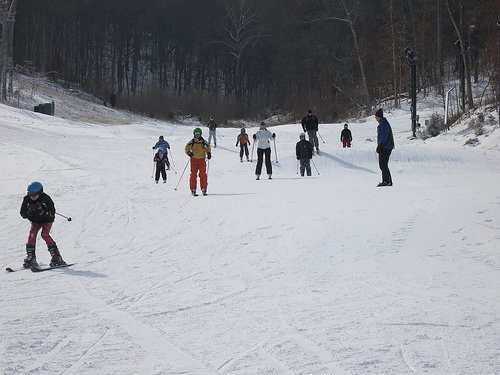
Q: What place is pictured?
A: It is a field.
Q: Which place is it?
A: It is a field.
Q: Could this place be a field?
A: Yes, it is a field.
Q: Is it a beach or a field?
A: It is a field.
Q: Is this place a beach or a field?
A: It is a field.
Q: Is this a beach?
A: No, it is a field.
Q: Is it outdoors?
A: Yes, it is outdoors.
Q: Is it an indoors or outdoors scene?
A: It is outdoors.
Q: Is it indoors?
A: No, it is outdoors.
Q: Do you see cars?
A: No, there are no cars.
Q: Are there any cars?
A: No, there are no cars.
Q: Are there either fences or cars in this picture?
A: No, there are no cars or fences.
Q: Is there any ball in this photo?
A: No, there are no balls.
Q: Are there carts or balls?
A: No, there are no balls or carts.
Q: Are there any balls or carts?
A: No, there are no balls or carts.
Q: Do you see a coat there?
A: Yes, there is a coat.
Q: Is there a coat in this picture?
A: Yes, there is a coat.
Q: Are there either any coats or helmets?
A: Yes, there is a coat.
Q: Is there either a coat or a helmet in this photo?
A: Yes, there is a coat.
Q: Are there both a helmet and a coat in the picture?
A: Yes, there are both a coat and a helmet.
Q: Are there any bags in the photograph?
A: No, there are no bags.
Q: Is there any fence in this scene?
A: No, there are no fences.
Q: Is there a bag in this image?
A: No, there are no bags.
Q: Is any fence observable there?
A: No, there are no fences.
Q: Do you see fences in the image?
A: No, there are no fences.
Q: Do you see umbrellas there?
A: No, there are no umbrellas.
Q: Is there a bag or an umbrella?
A: No, there are no umbrellas or bags.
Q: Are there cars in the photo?
A: No, there are no cars.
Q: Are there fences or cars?
A: No, there are no cars or fences.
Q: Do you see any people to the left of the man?
A: Yes, there is a person to the left of the man.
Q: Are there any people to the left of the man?
A: Yes, there is a person to the left of the man.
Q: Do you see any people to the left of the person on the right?
A: Yes, there is a person to the left of the man.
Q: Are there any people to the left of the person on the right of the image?
A: Yes, there is a person to the left of the man.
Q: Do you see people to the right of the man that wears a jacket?
A: No, the person is to the left of the man.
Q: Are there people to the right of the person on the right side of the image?
A: No, the person is to the left of the man.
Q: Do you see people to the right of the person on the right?
A: No, the person is to the left of the man.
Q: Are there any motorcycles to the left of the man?
A: No, there is a person to the left of the man.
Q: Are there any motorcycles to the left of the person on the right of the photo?
A: No, there is a person to the left of the man.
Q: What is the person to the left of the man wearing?
A: The person is wearing a jacket.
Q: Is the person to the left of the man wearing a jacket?
A: Yes, the person is wearing a jacket.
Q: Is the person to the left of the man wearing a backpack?
A: No, the person is wearing a jacket.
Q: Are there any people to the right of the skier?
A: Yes, there is a person to the right of the skier.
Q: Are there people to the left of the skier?
A: No, the person is to the right of the skier.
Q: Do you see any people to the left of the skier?
A: No, the person is to the right of the skier.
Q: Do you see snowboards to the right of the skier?
A: No, there is a person to the right of the skier.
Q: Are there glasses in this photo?
A: No, there are no glasses.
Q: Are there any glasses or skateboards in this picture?
A: No, there are no glasses or skateboards.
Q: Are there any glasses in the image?
A: No, there are no glasses.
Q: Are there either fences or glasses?
A: No, there are no glasses or fences.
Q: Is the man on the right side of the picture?
A: Yes, the man is on the right of the image.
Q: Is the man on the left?
A: No, the man is on the right of the image.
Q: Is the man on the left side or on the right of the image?
A: The man is on the right of the image.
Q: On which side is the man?
A: The man is on the right of the image.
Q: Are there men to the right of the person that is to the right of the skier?
A: Yes, there is a man to the right of the person.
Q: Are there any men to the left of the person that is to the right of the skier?
A: No, the man is to the right of the person.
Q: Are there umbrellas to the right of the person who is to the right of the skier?
A: No, there is a man to the right of the person.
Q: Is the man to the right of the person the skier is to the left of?
A: Yes, the man is to the right of the person.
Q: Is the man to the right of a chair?
A: No, the man is to the right of the person.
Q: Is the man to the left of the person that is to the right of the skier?
A: No, the man is to the right of the person.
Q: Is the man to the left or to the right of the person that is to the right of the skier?
A: The man is to the right of the person.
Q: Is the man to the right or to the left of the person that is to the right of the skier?
A: The man is to the right of the person.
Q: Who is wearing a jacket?
A: The man is wearing a jacket.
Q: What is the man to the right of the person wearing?
A: The man is wearing a jacket.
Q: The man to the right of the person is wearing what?
A: The man is wearing a jacket.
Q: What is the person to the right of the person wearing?
A: The man is wearing a jacket.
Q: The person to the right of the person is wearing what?
A: The man is wearing a jacket.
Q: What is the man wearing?
A: The man is wearing a jacket.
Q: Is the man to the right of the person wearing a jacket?
A: Yes, the man is wearing a jacket.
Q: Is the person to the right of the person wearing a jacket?
A: Yes, the man is wearing a jacket.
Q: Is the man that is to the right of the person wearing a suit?
A: No, the man is wearing a jacket.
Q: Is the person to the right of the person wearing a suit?
A: No, the man is wearing a jacket.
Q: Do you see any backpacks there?
A: No, there are no backpacks.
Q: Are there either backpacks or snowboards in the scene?
A: No, there are no backpacks or snowboards.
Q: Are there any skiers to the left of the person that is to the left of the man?
A: Yes, there is a skier to the left of the person.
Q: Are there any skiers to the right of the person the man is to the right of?
A: No, the skier is to the left of the person.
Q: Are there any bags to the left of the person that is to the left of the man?
A: No, there is a skier to the left of the person.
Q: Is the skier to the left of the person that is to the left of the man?
A: Yes, the skier is to the left of the person.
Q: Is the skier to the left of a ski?
A: No, the skier is to the left of the person.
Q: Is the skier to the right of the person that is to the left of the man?
A: No, the skier is to the left of the person.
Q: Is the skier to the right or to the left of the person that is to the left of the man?
A: The skier is to the left of the person.